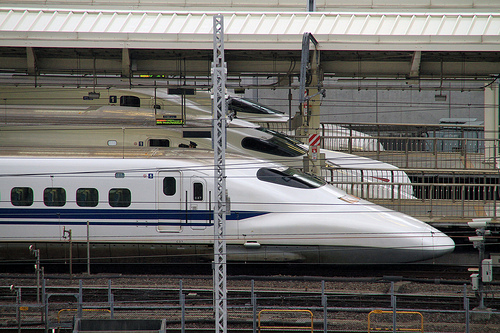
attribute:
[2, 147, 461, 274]
trains — white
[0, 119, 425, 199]
trains — white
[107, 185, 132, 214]
window — black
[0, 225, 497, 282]
tracks — black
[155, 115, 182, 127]
words — neon, green, red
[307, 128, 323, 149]
sign — red, white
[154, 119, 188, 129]
sign — neon, hanging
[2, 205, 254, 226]
line — dark, blue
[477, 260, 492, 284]
sensors — bunch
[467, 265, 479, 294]
sensors — bunch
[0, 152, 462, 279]
train — speeding, blue, white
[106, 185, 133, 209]
window — black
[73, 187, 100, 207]
window — black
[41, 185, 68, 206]
window — black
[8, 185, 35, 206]
window — black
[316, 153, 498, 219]
barriers — long, silver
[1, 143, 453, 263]
train — white, blue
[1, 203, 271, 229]
stripe — blue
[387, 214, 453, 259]
tip — white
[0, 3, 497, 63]
roof — white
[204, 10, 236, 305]
pole — grey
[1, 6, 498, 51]
roof — white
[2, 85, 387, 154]
train — white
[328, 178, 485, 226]
gate — gray, metal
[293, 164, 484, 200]
gate — gray, metal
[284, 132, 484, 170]
gate — gray, metal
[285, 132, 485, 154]
gate — gray, metal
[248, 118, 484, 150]
gate — gray, metal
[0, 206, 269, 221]
stripe — blue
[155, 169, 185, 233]
door — white, blue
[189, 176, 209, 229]
door — white, blue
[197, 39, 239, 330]
pole — steel, pillar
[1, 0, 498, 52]
tiles — white